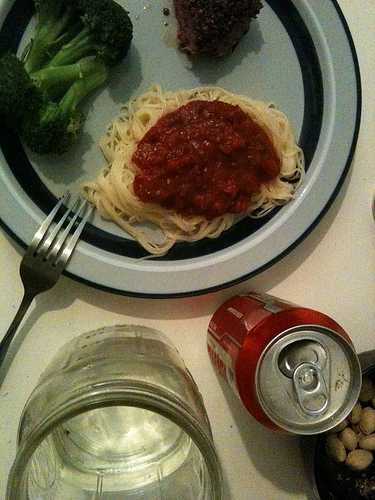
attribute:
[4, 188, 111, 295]
fork — silver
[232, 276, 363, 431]
can — drink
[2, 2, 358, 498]
table — white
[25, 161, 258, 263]
rings — black 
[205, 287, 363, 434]
can — red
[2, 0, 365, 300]
plate — white